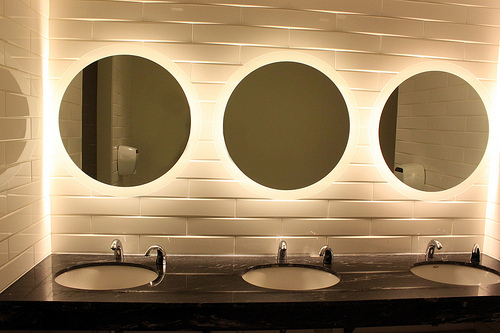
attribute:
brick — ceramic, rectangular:
[288, 30, 385, 56]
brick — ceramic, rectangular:
[189, 23, 288, 50]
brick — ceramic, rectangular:
[90, 19, 193, 43]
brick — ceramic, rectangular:
[382, 36, 464, 59]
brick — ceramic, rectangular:
[234, 198, 329, 218]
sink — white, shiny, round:
[52, 261, 158, 291]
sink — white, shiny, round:
[411, 259, 500, 285]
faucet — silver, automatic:
[111, 241, 125, 259]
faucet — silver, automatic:
[276, 239, 288, 261]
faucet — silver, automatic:
[424, 239, 443, 259]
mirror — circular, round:
[377, 69, 488, 191]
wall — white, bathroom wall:
[47, 0, 499, 257]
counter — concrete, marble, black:
[0, 255, 498, 328]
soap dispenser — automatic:
[144, 245, 165, 267]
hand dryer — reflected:
[116, 144, 138, 176]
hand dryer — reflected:
[395, 160, 425, 186]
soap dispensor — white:
[112, 130, 156, 187]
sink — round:
[409, 250, 499, 292]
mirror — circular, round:
[55, 53, 192, 190]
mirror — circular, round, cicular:
[221, 60, 351, 198]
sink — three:
[412, 261, 499, 287]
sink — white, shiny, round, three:
[242, 265, 340, 291]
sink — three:
[54, 263, 158, 288]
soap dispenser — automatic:
[318, 239, 333, 264]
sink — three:
[59, 239, 170, 296]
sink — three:
[247, 242, 353, 292]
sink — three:
[413, 234, 498, 289]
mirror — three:
[379, 50, 497, 217]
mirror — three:
[213, 42, 377, 199]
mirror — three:
[48, 45, 210, 195]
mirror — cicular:
[41, 46, 191, 209]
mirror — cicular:
[372, 70, 498, 193]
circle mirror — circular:
[210, 39, 360, 208]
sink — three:
[52, 237, 171, 293]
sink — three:
[240, 235, 343, 292]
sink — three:
[407, 240, 499, 287]